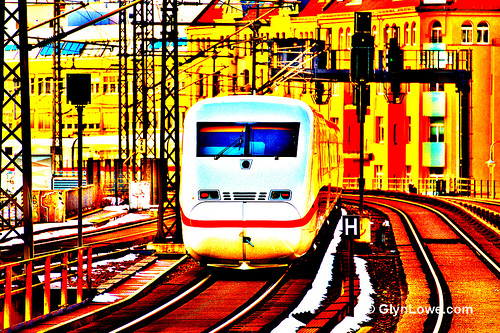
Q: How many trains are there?
A: One.